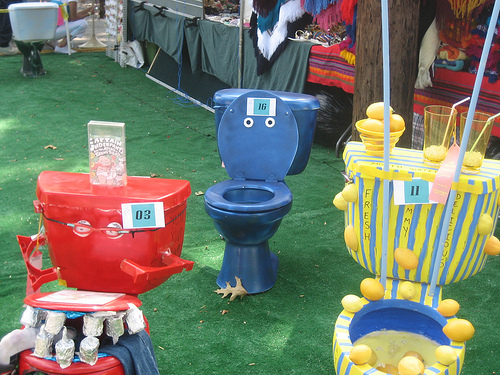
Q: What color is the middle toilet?
A: Blue.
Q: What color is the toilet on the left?
A: Red.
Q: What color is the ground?
A: Green.